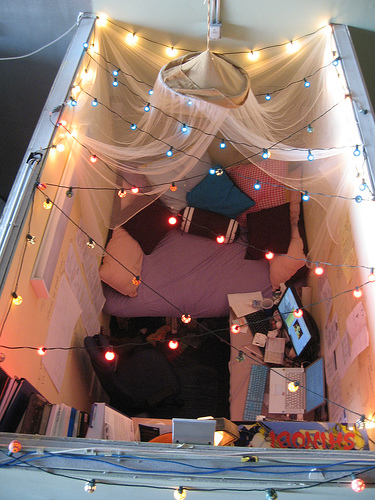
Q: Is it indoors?
A: Yes, it is indoors.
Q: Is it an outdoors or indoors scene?
A: It is indoors.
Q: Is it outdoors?
A: No, it is indoors.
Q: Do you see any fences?
A: No, there are no fences.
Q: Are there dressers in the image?
A: No, there are no dressers.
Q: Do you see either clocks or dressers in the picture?
A: No, there are no dressers or clocks.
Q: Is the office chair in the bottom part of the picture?
A: Yes, the office chair is in the bottom of the image.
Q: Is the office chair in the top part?
A: No, the office chair is in the bottom of the image.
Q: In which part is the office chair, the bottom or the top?
A: The office chair is in the bottom of the image.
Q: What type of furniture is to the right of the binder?
A: The piece of furniture is an office chair.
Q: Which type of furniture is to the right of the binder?
A: The piece of furniture is an office chair.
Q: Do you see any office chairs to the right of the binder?
A: Yes, there is an office chair to the right of the binder.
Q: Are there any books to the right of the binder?
A: No, there is an office chair to the right of the binder.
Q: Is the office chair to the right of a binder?
A: Yes, the office chair is to the right of a binder.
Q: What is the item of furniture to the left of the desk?
A: The piece of furniture is an office chair.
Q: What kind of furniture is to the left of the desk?
A: The piece of furniture is an office chair.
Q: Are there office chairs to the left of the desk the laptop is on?
A: Yes, there is an office chair to the left of the desk.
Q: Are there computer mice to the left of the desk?
A: No, there is an office chair to the left of the desk.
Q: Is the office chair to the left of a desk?
A: Yes, the office chair is to the left of a desk.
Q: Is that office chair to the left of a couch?
A: No, the office chair is to the left of a desk.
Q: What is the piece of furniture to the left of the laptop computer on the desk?
A: The piece of furniture is an office chair.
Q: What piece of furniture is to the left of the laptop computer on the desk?
A: The piece of furniture is an office chair.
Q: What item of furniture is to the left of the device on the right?
A: The piece of furniture is an office chair.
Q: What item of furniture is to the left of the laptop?
A: The piece of furniture is an office chair.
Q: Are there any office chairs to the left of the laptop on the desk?
A: Yes, there is an office chair to the left of the laptop.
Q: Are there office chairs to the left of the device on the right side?
A: Yes, there is an office chair to the left of the laptop.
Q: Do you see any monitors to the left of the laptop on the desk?
A: No, there is an office chair to the left of the laptop.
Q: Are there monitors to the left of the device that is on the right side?
A: No, there is an office chair to the left of the laptop.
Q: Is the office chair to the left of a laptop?
A: Yes, the office chair is to the left of a laptop.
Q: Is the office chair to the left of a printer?
A: No, the office chair is to the left of a laptop.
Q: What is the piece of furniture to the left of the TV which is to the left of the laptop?
A: The piece of furniture is an office chair.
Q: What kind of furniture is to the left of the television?
A: The piece of furniture is an office chair.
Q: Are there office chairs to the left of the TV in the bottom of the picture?
A: Yes, there is an office chair to the left of the TV.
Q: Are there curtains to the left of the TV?
A: No, there is an office chair to the left of the TV.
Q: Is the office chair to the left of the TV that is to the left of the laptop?
A: Yes, the office chair is to the left of the TV.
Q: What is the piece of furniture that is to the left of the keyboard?
A: The piece of furniture is an office chair.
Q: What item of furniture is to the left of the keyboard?
A: The piece of furniture is an office chair.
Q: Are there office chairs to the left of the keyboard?
A: Yes, there is an office chair to the left of the keyboard.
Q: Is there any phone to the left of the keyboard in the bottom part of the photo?
A: No, there is an office chair to the left of the keyboard.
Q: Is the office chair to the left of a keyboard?
A: Yes, the office chair is to the left of a keyboard.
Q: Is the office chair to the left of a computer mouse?
A: No, the office chair is to the left of a keyboard.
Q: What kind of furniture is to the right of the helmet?
A: The piece of furniture is an office chair.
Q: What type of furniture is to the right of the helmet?
A: The piece of furniture is an office chair.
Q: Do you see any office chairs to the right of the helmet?
A: Yes, there is an office chair to the right of the helmet.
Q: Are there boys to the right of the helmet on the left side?
A: No, there is an office chair to the right of the helmet.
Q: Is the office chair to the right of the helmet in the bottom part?
A: Yes, the office chair is to the right of the helmet.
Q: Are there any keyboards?
A: Yes, there is a keyboard.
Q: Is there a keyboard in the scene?
A: Yes, there is a keyboard.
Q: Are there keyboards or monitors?
A: Yes, there is a keyboard.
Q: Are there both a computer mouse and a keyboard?
A: No, there is a keyboard but no computer mice.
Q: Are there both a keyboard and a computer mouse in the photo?
A: No, there is a keyboard but no computer mice.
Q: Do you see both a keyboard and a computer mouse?
A: No, there is a keyboard but no computer mice.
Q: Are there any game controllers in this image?
A: No, there are no game controllers.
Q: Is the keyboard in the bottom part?
A: Yes, the keyboard is in the bottom of the image.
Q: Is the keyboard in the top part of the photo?
A: No, the keyboard is in the bottom of the image.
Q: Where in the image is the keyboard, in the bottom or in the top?
A: The keyboard is in the bottom of the image.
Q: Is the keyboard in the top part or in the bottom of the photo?
A: The keyboard is in the bottom of the image.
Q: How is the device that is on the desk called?
A: The device is a keyboard.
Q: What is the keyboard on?
A: The keyboard is on the desk.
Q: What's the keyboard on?
A: The keyboard is on the desk.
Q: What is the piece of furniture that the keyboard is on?
A: The piece of furniture is a desk.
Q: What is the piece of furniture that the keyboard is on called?
A: The piece of furniture is a desk.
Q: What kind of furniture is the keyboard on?
A: The keyboard is on the desk.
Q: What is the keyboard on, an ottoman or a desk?
A: The keyboard is on a desk.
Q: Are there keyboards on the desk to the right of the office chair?
A: Yes, there is a keyboard on the desk.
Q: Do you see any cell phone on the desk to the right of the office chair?
A: No, there is a keyboard on the desk.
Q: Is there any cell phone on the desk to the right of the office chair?
A: No, there is a keyboard on the desk.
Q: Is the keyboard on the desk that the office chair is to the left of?
A: Yes, the keyboard is on the desk.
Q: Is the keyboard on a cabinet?
A: No, the keyboard is on the desk.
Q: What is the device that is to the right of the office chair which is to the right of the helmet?
A: The device is a keyboard.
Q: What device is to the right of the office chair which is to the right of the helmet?
A: The device is a keyboard.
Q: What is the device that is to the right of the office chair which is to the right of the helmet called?
A: The device is a keyboard.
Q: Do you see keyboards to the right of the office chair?
A: Yes, there is a keyboard to the right of the office chair.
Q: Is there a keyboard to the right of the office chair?
A: Yes, there is a keyboard to the right of the office chair.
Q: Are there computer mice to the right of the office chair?
A: No, there is a keyboard to the right of the office chair.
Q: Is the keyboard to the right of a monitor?
A: No, the keyboard is to the right of the office chair.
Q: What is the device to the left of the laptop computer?
A: The device is a keyboard.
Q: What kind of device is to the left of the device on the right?
A: The device is a keyboard.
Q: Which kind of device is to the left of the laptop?
A: The device is a keyboard.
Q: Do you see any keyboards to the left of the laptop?
A: Yes, there is a keyboard to the left of the laptop.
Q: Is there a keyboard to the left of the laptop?
A: Yes, there is a keyboard to the left of the laptop.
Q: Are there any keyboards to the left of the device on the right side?
A: Yes, there is a keyboard to the left of the laptop.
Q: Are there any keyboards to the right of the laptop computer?
A: No, the keyboard is to the left of the laptop computer.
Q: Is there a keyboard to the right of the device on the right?
A: No, the keyboard is to the left of the laptop computer.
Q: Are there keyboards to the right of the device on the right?
A: No, the keyboard is to the left of the laptop computer.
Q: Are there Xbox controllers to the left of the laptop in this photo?
A: No, there is a keyboard to the left of the laptop.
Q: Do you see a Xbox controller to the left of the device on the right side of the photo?
A: No, there is a keyboard to the left of the laptop.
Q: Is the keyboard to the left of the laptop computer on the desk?
A: Yes, the keyboard is to the left of the laptop.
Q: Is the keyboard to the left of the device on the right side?
A: Yes, the keyboard is to the left of the laptop.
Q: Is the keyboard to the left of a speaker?
A: No, the keyboard is to the left of the laptop.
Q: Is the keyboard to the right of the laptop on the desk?
A: No, the keyboard is to the left of the laptop.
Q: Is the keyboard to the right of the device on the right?
A: No, the keyboard is to the left of the laptop.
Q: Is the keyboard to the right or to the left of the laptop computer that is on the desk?
A: The keyboard is to the left of the laptop computer.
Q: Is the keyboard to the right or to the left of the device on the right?
A: The keyboard is to the left of the laptop computer.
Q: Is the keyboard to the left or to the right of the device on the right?
A: The keyboard is to the left of the laptop computer.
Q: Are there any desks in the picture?
A: Yes, there is a desk.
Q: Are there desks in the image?
A: Yes, there is a desk.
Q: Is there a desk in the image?
A: Yes, there is a desk.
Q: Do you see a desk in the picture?
A: Yes, there is a desk.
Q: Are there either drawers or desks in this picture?
A: Yes, there is a desk.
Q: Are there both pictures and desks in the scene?
A: No, there is a desk but no pictures.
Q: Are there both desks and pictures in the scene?
A: No, there is a desk but no pictures.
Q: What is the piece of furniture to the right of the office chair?
A: The piece of furniture is a desk.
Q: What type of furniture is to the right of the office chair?
A: The piece of furniture is a desk.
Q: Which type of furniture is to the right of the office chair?
A: The piece of furniture is a desk.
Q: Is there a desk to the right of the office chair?
A: Yes, there is a desk to the right of the office chair.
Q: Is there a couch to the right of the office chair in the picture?
A: No, there is a desk to the right of the office chair.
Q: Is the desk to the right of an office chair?
A: Yes, the desk is to the right of an office chair.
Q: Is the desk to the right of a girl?
A: No, the desk is to the right of an office chair.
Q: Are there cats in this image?
A: No, there are no cats.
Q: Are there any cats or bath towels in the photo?
A: No, there are no cats or bath towels.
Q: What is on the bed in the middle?
A: The sheet is on the bed.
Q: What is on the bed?
A: The sheet is on the bed.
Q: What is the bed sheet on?
A: The bed sheet is on the bed.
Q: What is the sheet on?
A: The bed sheet is on the bed.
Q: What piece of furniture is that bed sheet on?
A: The bed sheet is on the bed.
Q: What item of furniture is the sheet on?
A: The bed sheet is on the bed.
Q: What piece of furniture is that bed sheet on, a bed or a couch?
A: The bed sheet is on a bed.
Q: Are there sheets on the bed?
A: Yes, there is a sheet on the bed.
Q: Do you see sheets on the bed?
A: Yes, there is a sheet on the bed.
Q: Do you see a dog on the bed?
A: No, there is a sheet on the bed.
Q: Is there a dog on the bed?
A: No, there is a sheet on the bed.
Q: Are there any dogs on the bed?
A: No, there is a sheet on the bed.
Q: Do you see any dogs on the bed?
A: No, there is a sheet on the bed.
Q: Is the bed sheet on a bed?
A: Yes, the bed sheet is on a bed.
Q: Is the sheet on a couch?
A: No, the sheet is on a bed.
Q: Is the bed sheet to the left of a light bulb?
A: Yes, the bed sheet is to the left of a light bulb.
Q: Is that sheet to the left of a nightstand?
A: No, the sheet is to the left of a light bulb.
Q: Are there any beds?
A: Yes, there is a bed.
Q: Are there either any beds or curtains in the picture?
A: Yes, there is a bed.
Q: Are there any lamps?
A: No, there are no lamps.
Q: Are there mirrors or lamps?
A: No, there are no lamps or mirrors.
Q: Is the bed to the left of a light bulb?
A: Yes, the bed is to the left of a light bulb.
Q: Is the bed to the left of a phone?
A: No, the bed is to the left of a light bulb.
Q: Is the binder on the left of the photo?
A: Yes, the binder is on the left of the image.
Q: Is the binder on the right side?
A: No, the binder is on the left of the image.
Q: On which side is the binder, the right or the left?
A: The binder is on the left of the image.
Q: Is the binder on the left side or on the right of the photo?
A: The binder is on the left of the image.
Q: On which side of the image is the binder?
A: The binder is on the left of the image.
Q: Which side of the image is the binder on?
A: The binder is on the left of the image.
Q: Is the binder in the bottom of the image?
A: Yes, the binder is in the bottom of the image.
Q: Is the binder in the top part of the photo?
A: No, the binder is in the bottom of the image.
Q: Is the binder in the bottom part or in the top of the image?
A: The binder is in the bottom of the image.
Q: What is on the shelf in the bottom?
A: The binder is on the shelf.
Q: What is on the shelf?
A: The binder is on the shelf.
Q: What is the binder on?
A: The binder is on the shelf.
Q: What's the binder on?
A: The binder is on the shelf.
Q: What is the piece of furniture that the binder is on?
A: The piece of furniture is a shelf.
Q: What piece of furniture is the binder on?
A: The binder is on the shelf.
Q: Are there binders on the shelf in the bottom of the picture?
A: Yes, there is a binder on the shelf.